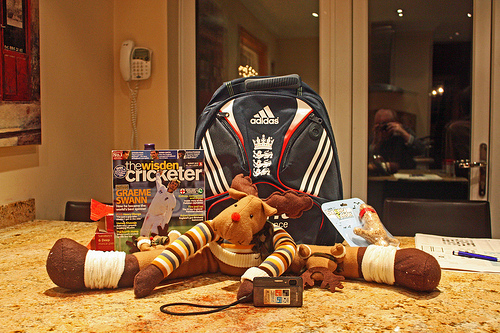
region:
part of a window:
[453, 108, 481, 133]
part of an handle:
[463, 162, 473, 180]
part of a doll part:
[229, 227, 246, 249]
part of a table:
[329, 299, 337, 311]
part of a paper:
[418, 241, 431, 258]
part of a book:
[194, 175, 214, 185]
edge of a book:
[121, 187, 131, 208]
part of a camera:
[272, 285, 279, 290]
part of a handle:
[461, 166, 473, 186]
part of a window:
[416, 130, 423, 148]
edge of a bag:
[208, 137, 218, 162]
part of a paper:
[366, 303, 377, 313]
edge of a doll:
[385, 257, 409, 293]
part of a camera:
[257, 278, 278, 310]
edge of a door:
[344, 141, 354, 160]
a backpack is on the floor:
[192, 74, 347, 251]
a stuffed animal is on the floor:
[49, 193, 438, 306]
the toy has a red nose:
[228, 212, 241, 221]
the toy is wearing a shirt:
[149, 206, 294, 284]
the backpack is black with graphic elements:
[193, 68, 341, 250]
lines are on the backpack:
[300, 131, 335, 196]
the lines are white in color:
[297, 130, 334, 199]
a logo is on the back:
[249, 103, 279, 126]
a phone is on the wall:
[118, 39, 153, 83]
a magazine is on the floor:
[111, 143, 208, 280]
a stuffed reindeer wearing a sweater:
[55, 192, 416, 301]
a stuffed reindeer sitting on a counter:
[48, 179, 428, 303]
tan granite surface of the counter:
[13, 297, 94, 331]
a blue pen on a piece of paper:
[449, 243, 498, 269]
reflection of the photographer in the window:
[359, 97, 444, 181]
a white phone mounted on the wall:
[106, 35, 168, 99]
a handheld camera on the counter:
[163, 270, 315, 320]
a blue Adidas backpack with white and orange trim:
[185, 77, 349, 255]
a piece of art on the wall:
[0, 1, 65, 176]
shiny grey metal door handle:
[456, 134, 491, 203]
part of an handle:
[464, 152, 469, 173]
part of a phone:
[129, 66, 135, 76]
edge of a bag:
[327, 134, 339, 153]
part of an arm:
[166, 258, 173, 269]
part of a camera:
[266, 270, 276, 304]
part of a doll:
[235, 209, 248, 241]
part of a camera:
[273, 290, 280, 300]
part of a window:
[371, 92, 389, 128]